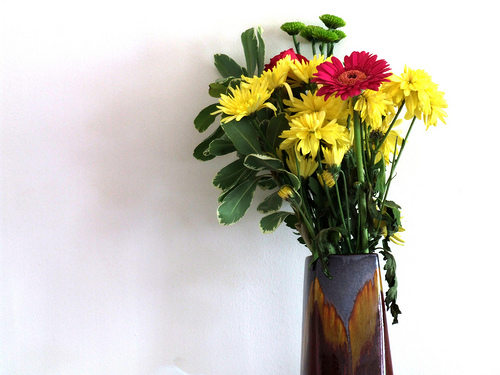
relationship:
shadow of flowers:
[69, 41, 235, 341] [195, 12, 443, 370]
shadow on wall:
[69, 41, 235, 341] [3, 8, 270, 372]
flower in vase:
[266, 50, 310, 68] [304, 250, 391, 372]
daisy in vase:
[309, 50, 390, 98] [304, 250, 391, 372]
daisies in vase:
[216, 63, 278, 123] [304, 250, 391, 372]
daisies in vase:
[278, 104, 343, 154] [304, 250, 391, 372]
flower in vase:
[353, 88, 400, 133] [304, 250, 391, 372]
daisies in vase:
[399, 66, 445, 125] [304, 250, 391, 372]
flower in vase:
[289, 54, 325, 82] [304, 250, 391, 372]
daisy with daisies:
[309, 50, 390, 98] [216, 63, 278, 123]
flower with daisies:
[263, 45, 308, 66] [278, 104, 343, 154]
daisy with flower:
[309, 50, 390, 98] [353, 88, 400, 133]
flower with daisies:
[263, 45, 308, 66] [399, 66, 445, 125]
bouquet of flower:
[193, 12, 446, 372] [266, 45, 308, 68]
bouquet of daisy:
[193, 12, 446, 372] [309, 50, 390, 98]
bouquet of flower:
[193, 12, 446, 372] [214, 55, 294, 121]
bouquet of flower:
[193, 12, 446, 372] [279, 110, 349, 175]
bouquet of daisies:
[193, 12, 446, 372] [399, 66, 445, 125]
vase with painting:
[304, 250, 391, 372] [312, 276, 371, 323]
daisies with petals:
[399, 66, 445, 125] [389, 71, 409, 89]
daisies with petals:
[399, 66, 445, 125] [418, 90, 432, 117]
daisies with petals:
[399, 66, 445, 125] [429, 88, 447, 125]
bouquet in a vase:
[193, 12, 446, 324] [304, 250, 391, 372]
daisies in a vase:
[216, 63, 278, 123] [304, 250, 391, 372]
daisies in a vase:
[278, 104, 343, 154] [304, 250, 391, 372]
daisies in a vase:
[399, 66, 445, 125] [304, 250, 391, 372]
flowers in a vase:
[279, 6, 353, 55] [304, 250, 391, 372]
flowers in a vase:
[278, 11, 348, 61] [304, 250, 391, 372]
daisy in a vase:
[309, 50, 390, 98] [304, 250, 391, 372]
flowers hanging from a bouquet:
[310, 50, 446, 177] [193, 12, 446, 372]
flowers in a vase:
[278, 11, 342, 59] [304, 250, 391, 372]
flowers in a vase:
[310, 50, 446, 177] [304, 250, 391, 372]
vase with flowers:
[304, 250, 391, 372] [279, 6, 353, 55]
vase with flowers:
[304, 250, 391, 372] [212, 53, 315, 121]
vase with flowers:
[304, 250, 391, 372] [280, 90, 363, 246]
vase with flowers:
[304, 250, 391, 372] [310, 50, 446, 177]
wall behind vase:
[0, 8, 253, 372] [304, 250, 391, 372]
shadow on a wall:
[69, 41, 228, 320] [1, 4, 463, 373]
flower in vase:
[386, 66, 447, 126] [304, 250, 391, 372]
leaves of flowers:
[216, 116, 262, 157] [217, 59, 306, 122]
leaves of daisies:
[211, 157, 254, 225] [278, 104, 343, 154]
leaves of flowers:
[245, 113, 295, 193] [364, 65, 445, 160]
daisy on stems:
[309, 50, 390, 98] [349, 120, 384, 195]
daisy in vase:
[309, 50, 390, 98] [295, 249, 391, 373]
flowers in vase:
[310, 50, 446, 177] [295, 249, 391, 373]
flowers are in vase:
[279, 6, 352, 48] [295, 249, 391, 373]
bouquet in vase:
[193, 12, 446, 324] [304, 250, 391, 372]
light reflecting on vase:
[379, 259, 386, 373] [304, 250, 391, 372]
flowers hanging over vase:
[310, 50, 446, 177] [304, 256, 386, 373]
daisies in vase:
[211, 49, 449, 249] [310, 254, 391, 373]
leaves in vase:
[211, 157, 260, 224] [304, 250, 391, 372]